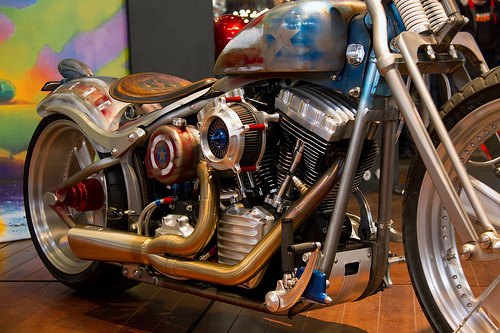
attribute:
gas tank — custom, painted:
[211, 0, 367, 79]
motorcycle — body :
[36, 69, 496, 331]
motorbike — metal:
[11, 12, 494, 309]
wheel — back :
[21, 113, 138, 295]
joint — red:
[44, 175, 111, 213]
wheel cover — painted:
[33, 75, 130, 130]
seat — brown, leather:
[113, 69, 215, 100]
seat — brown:
[108, 70, 217, 103]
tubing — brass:
[67, 222, 259, 284]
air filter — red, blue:
[201, 101, 264, 173]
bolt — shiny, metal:
[344, 41, 364, 66]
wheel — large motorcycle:
[12, 107, 139, 291]